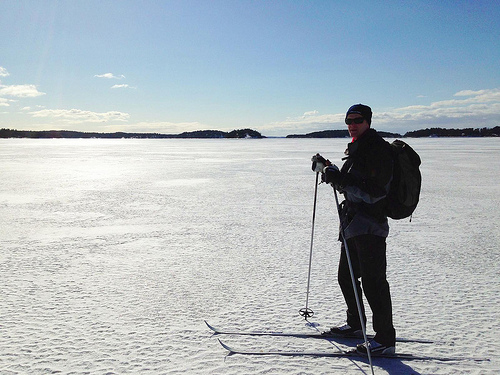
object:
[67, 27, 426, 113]
sky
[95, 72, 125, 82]
cloud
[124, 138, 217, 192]
snow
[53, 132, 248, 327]
ground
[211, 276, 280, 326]
tracks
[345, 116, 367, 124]
sunglasses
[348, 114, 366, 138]
face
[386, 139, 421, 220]
backpack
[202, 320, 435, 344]
ski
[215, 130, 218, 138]
tree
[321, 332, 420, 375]
shadow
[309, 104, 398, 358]
man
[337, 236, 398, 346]
pants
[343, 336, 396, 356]
boots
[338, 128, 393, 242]
jacket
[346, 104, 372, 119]
hat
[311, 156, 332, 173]
gloves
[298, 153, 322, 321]
pole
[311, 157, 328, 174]
hand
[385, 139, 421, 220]
bag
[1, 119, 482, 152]
horizon